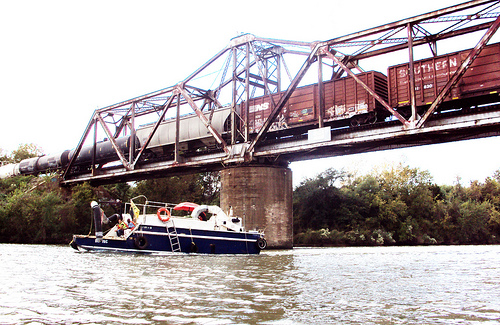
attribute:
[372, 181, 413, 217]
leaves — green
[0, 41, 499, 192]
train — multicar, rusty, numerous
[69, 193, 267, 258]
boat — blue, white, floating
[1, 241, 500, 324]
water — murky, muddy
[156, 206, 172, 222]
life preserver — orange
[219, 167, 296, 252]
pillar — wide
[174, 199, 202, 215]
umbrella — red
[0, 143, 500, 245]
trees — bushy, heavily wooded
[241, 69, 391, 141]
box car — red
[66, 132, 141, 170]
tanker — black